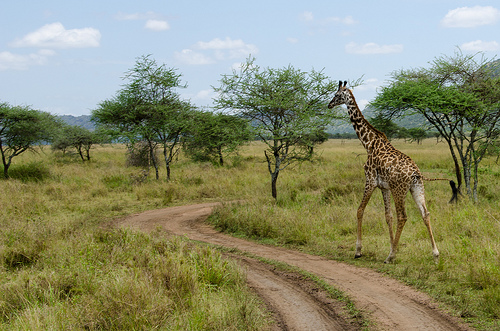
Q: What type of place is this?
A: It is a field.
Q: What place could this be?
A: It is a field.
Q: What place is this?
A: It is a field.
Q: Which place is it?
A: It is a field.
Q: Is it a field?
A: Yes, it is a field.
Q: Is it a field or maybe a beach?
A: It is a field.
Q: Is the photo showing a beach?
A: No, the picture is showing a field.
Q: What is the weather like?
A: It is cloudy.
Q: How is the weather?
A: It is cloudy.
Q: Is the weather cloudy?
A: Yes, it is cloudy.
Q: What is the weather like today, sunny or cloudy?
A: It is cloudy.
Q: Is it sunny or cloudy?
A: It is cloudy.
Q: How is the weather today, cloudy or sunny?
A: It is cloudy.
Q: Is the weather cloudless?
A: No, it is cloudy.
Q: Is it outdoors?
A: Yes, it is outdoors.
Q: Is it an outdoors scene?
A: Yes, it is outdoors.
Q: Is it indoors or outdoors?
A: It is outdoors.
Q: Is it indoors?
A: No, it is outdoors.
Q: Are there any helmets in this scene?
A: No, there are no helmets.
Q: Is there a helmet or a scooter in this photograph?
A: No, there are no helmets or scooters.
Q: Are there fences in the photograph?
A: No, there are no fences.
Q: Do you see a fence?
A: No, there are no fences.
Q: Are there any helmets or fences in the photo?
A: No, there are no fences or helmets.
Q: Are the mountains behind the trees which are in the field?
A: Yes, the mountains are behind the trees.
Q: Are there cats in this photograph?
A: No, there are no cats.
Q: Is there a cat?
A: No, there are no cats.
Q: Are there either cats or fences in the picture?
A: No, there are no cats or fences.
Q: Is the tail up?
A: Yes, the tail is up.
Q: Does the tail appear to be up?
A: Yes, the tail is up.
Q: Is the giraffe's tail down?
A: No, the tail is up.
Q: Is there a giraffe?
A: Yes, there is a giraffe.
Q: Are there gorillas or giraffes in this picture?
A: Yes, there is a giraffe.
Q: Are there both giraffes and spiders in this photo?
A: No, there is a giraffe but no spiders.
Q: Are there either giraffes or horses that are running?
A: Yes, the giraffe is running.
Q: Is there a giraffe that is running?
A: Yes, there is a giraffe that is running.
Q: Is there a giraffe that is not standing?
A: Yes, there is a giraffe that is running.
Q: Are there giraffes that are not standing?
A: Yes, there is a giraffe that is running.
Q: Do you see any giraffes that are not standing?
A: Yes, there is a giraffe that is running .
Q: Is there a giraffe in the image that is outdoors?
A: Yes, there is a giraffe that is outdoors.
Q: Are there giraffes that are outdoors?
A: Yes, there is a giraffe that is outdoors.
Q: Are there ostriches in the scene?
A: No, there are no ostriches.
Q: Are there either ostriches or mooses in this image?
A: No, there are no ostriches or mooses.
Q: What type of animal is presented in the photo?
A: The animal is a giraffe.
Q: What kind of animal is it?
A: The animal is a giraffe.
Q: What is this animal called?
A: This is a giraffe.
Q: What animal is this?
A: This is a giraffe.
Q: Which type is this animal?
A: This is a giraffe.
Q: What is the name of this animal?
A: This is a giraffe.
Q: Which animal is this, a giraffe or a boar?
A: This is a giraffe.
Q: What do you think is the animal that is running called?
A: The animal is a giraffe.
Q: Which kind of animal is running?
A: The animal is a giraffe.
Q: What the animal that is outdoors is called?
A: The animal is a giraffe.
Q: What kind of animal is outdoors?
A: The animal is a giraffe.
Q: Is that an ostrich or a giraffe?
A: That is a giraffe.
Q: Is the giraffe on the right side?
A: Yes, the giraffe is on the right of the image.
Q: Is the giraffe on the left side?
A: No, the giraffe is on the right of the image.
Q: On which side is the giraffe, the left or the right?
A: The giraffe is on the right of the image.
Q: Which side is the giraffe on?
A: The giraffe is on the right of the image.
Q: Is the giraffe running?
A: Yes, the giraffe is running.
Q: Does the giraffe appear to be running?
A: Yes, the giraffe is running.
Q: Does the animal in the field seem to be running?
A: Yes, the giraffe is running.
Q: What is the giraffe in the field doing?
A: The giraffe is running.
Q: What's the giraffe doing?
A: The giraffe is running.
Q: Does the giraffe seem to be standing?
A: No, the giraffe is running.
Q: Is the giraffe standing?
A: No, the giraffe is running.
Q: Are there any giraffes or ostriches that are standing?
A: No, there is a giraffe but it is running.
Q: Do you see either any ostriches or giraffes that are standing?
A: No, there is a giraffe but it is running.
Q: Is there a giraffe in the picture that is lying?
A: No, there is a giraffe but it is running.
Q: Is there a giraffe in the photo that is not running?
A: No, there is a giraffe but it is running.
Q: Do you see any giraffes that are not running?
A: No, there is a giraffe but it is running.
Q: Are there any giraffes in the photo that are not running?
A: No, there is a giraffe but it is running.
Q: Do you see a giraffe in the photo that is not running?
A: No, there is a giraffe but it is running.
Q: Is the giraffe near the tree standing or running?
A: The giraffe is running.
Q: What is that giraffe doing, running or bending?
A: The giraffe is running.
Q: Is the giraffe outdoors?
A: Yes, the giraffe is outdoors.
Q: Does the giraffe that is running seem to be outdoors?
A: Yes, the giraffe is outdoors.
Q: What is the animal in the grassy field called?
A: The animal is a giraffe.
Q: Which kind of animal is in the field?
A: The animal is a giraffe.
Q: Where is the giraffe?
A: The giraffe is in the field.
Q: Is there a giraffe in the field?
A: Yes, there is a giraffe in the field.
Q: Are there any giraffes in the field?
A: Yes, there is a giraffe in the field.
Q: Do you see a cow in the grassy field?
A: No, there is a giraffe in the field.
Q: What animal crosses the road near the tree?
A: The giraffe crosses the road.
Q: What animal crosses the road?
A: The giraffe crosses the road.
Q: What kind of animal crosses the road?
A: The animal is a giraffe.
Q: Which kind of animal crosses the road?
A: The animal is a giraffe.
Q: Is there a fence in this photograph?
A: No, there are no fences.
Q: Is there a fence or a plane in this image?
A: No, there are no fences or airplanes.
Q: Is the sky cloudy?
A: Yes, the sky is cloudy.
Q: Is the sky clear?
A: No, the sky is cloudy.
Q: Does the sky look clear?
A: No, the sky is cloudy.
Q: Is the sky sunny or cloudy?
A: The sky is cloudy.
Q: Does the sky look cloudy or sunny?
A: The sky is cloudy.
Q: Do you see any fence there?
A: No, there are no fences.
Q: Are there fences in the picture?
A: No, there are no fences.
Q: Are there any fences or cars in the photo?
A: No, there are no fences or cars.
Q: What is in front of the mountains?
A: The trees are in front of the mountains.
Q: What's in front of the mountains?
A: The trees are in front of the mountains.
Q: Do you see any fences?
A: No, there are no fences.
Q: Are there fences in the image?
A: No, there are no fences.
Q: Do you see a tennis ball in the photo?
A: No, there are no tennis balls.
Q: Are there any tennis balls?
A: No, there are no tennis balls.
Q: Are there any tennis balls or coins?
A: No, there are no tennis balls or coins.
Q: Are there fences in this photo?
A: No, there are no fences.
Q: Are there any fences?
A: No, there are no fences.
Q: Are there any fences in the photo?
A: No, there are no fences.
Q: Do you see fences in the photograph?
A: No, there are no fences.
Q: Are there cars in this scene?
A: No, there are no cars.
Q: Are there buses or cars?
A: No, there are no cars or buses.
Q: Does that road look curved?
A: Yes, the road is curved.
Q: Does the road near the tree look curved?
A: Yes, the road is curved.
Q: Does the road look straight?
A: No, the road is curved.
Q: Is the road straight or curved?
A: The road is curved.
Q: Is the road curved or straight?
A: The road is curved.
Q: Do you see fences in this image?
A: No, there are no fences.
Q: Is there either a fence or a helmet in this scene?
A: No, there are no fences or helmets.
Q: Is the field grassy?
A: Yes, the field is grassy.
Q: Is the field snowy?
A: No, the field is grassy.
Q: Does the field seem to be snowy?
A: No, the field is grassy.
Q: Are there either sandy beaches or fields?
A: No, there is a field but it is grassy.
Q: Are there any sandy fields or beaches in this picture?
A: No, there is a field but it is grassy.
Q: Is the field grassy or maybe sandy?
A: The field is grassy.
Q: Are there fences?
A: No, there are no fences.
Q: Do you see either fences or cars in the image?
A: No, there are no fences or cars.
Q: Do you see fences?
A: No, there are no fences.